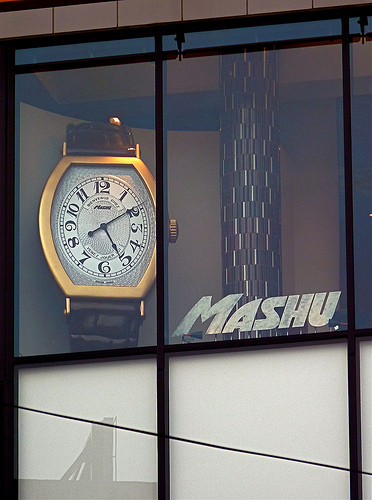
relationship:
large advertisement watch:
[39, 120, 179, 344] [38, 120, 180, 352]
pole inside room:
[220, 34, 283, 348] [10, 47, 372, 356]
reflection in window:
[15, 415, 158, 499] [11, 3, 367, 498]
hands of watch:
[85, 196, 141, 266] [38, 120, 180, 352]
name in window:
[167, 292, 346, 334] [11, 3, 367, 498]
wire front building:
[11, 404, 369, 477] [1, 2, 371, 499]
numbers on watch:
[64, 178, 143, 274] [38, 120, 180, 352]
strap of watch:
[63, 123, 138, 155] [38, 120, 180, 352]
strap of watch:
[70, 309, 139, 349] [38, 120, 180, 352]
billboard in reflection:
[60, 417, 119, 481] [15, 415, 158, 499]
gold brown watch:
[39, 153, 180, 300] [38, 120, 180, 352]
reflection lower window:
[15, 415, 158, 499] [14, 340, 350, 499]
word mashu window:
[167, 292, 346, 334] [11, 3, 367, 498]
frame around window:
[4, 6, 357, 366] [11, 3, 367, 498]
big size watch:
[39, 120, 179, 344] [38, 120, 180, 352]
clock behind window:
[64, 178, 143, 274] [11, 3, 367, 498]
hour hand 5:
[102, 225, 122, 259] [118, 251, 131, 267]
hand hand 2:
[89, 201, 142, 258] [126, 205, 142, 219]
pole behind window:
[220, 34, 283, 348] [11, 3, 367, 498]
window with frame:
[11, 3, 367, 498] [4, 6, 357, 366]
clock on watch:
[36, 150, 174, 302] [38, 120, 180, 352]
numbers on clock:
[64, 178, 143, 274] [64, 178, 143, 274]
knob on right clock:
[168, 219, 178, 243] [36, 150, 174, 302]